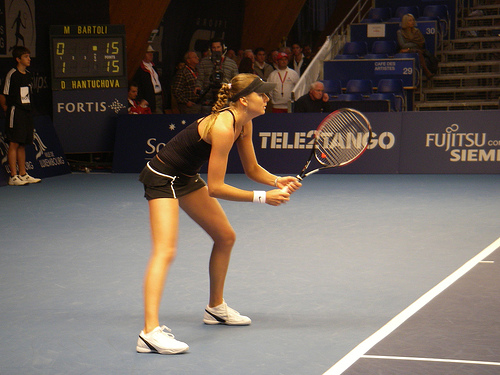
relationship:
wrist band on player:
[248, 187, 267, 205] [129, 62, 382, 367]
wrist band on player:
[252, 187, 272, 216] [108, 53, 350, 363]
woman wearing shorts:
[139, 63, 304, 363] [141, 152, 205, 205]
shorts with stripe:
[141, 152, 205, 205] [146, 159, 178, 183]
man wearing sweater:
[263, 51, 312, 112] [261, 65, 301, 106]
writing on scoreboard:
[60, 76, 126, 88] [46, 18, 128, 115]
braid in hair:
[201, 71, 237, 132] [202, 69, 277, 123]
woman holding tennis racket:
[139, 63, 304, 363] [286, 94, 380, 188]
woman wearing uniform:
[139, 63, 304, 363] [136, 115, 238, 197]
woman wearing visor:
[139, 63, 304, 363] [226, 72, 281, 101]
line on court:
[318, 234, 498, 373] [0, 165, 495, 373]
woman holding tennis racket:
[139, 63, 304, 363] [284, 108, 373, 195]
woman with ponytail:
[139, 63, 304, 363] [206, 79, 231, 112]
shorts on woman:
[141, 152, 205, 205] [139, 63, 304, 363]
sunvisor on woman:
[226, 76, 279, 101] [139, 63, 304, 363]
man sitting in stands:
[290, 79, 328, 110] [295, 4, 495, 114]